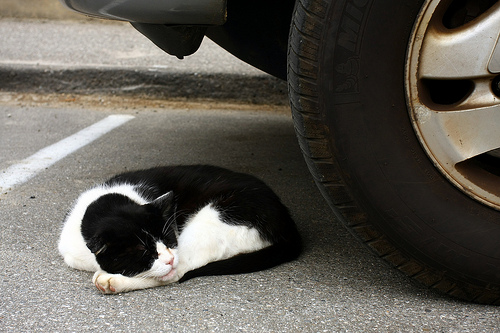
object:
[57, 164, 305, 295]
cat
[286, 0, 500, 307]
tire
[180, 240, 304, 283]
tail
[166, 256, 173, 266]
nose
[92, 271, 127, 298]
paw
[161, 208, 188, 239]
lash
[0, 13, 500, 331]
ground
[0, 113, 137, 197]
line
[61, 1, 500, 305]
car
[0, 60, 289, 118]
curb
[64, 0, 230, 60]
bumper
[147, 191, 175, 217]
ear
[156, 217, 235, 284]
leg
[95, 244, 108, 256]
ear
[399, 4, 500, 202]
rim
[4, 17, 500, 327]
pavement